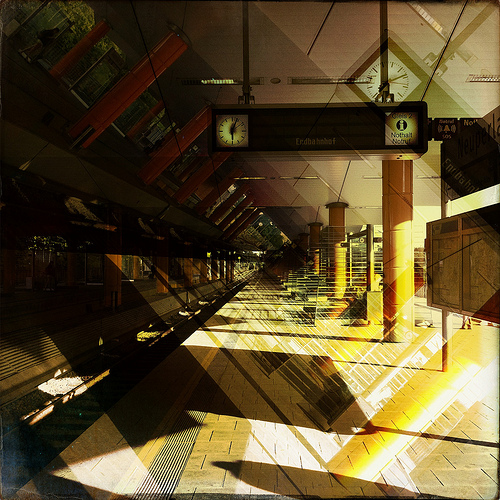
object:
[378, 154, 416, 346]
column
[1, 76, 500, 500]
station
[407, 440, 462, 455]
tiles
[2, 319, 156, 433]
train tracks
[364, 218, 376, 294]
support post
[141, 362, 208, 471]
yellow stripe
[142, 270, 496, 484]
train platform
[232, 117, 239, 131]
black hands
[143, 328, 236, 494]
rubber padding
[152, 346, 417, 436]
reflection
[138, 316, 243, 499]
steel grates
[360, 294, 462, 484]
ground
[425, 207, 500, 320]
wooden sign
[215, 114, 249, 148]
analog clock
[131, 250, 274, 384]
long hallway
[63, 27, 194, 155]
red pillars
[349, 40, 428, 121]
white clock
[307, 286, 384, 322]
stand/rack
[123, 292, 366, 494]
shadows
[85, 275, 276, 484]
floor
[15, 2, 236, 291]
roof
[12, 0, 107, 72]
windows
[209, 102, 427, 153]
sign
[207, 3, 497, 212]
ceiling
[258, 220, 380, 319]
terminal